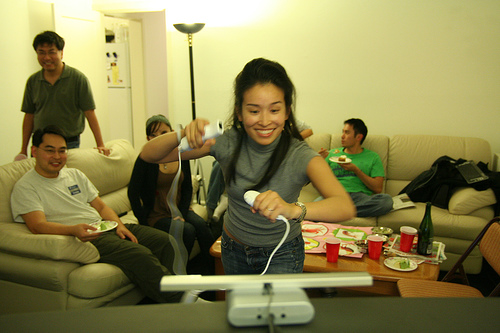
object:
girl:
[140, 57, 354, 300]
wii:
[140, 116, 392, 287]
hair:
[228, 58, 305, 191]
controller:
[243, 189, 281, 222]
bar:
[160, 273, 374, 293]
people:
[9, 114, 392, 258]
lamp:
[173, 23, 207, 122]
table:
[304, 222, 441, 282]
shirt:
[209, 132, 323, 247]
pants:
[221, 230, 306, 275]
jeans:
[220, 231, 305, 274]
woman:
[211, 58, 321, 243]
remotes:
[140, 124, 356, 246]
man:
[318, 118, 394, 217]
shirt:
[324, 148, 386, 195]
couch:
[354, 68, 493, 246]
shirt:
[10, 168, 99, 232]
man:
[10, 166, 103, 236]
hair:
[33, 31, 65, 50]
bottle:
[418, 202, 434, 255]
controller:
[181, 118, 215, 161]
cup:
[323, 238, 341, 263]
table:
[304, 246, 440, 281]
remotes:
[127, 114, 217, 276]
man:
[11, 126, 182, 304]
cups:
[324, 226, 416, 263]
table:
[304, 238, 439, 283]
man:
[21, 31, 108, 156]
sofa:
[66, 139, 138, 190]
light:
[171, 23, 211, 120]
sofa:
[387, 133, 491, 179]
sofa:
[390, 136, 445, 181]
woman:
[127, 113, 192, 224]